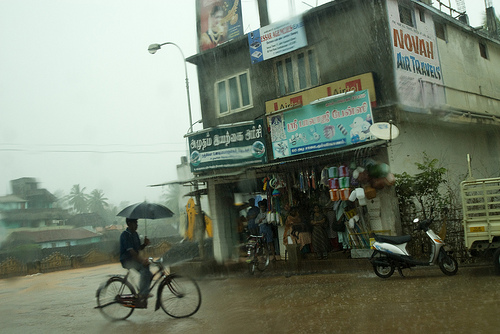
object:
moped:
[368, 217, 458, 279]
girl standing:
[307, 202, 331, 260]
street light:
[146, 41, 207, 263]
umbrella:
[114, 200, 175, 245]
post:
[161, 42, 208, 263]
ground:
[0, 268, 500, 333]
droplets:
[248, 297, 265, 314]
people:
[282, 206, 307, 260]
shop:
[178, 144, 399, 273]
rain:
[1, 0, 498, 332]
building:
[184, 0, 498, 266]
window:
[216, 80, 228, 114]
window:
[225, 80, 237, 108]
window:
[237, 73, 252, 106]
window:
[274, 58, 285, 94]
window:
[283, 57, 295, 91]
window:
[296, 54, 306, 92]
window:
[304, 51, 319, 87]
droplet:
[373, 295, 378, 300]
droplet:
[419, 285, 422, 287]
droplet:
[267, 273, 307, 284]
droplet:
[476, 304, 480, 306]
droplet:
[325, 307, 327, 310]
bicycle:
[95, 255, 202, 321]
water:
[18, 267, 93, 332]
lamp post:
[148, 42, 209, 265]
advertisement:
[390, 27, 446, 108]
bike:
[245, 232, 270, 273]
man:
[117, 217, 150, 307]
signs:
[187, 120, 271, 174]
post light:
[161, 41, 199, 68]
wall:
[384, 0, 500, 235]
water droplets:
[220, 272, 498, 332]